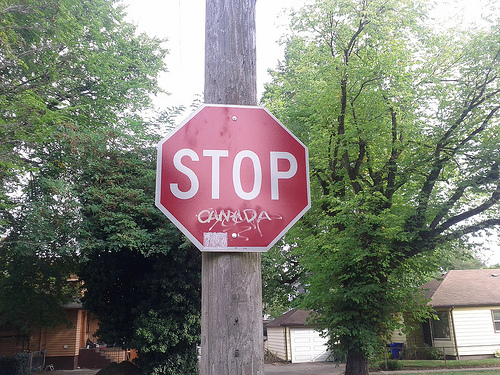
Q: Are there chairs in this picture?
A: No, there are no chairs.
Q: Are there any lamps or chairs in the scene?
A: No, there are no chairs or lamps.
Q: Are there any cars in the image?
A: No, there are no cars.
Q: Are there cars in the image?
A: No, there are no cars.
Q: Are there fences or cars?
A: No, there are no cars or fences.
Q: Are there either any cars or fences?
A: No, there are no cars or fences.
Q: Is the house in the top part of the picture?
A: No, the house is in the bottom of the image.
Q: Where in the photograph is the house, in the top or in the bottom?
A: The house is in the bottom of the image.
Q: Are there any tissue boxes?
A: No, there are no tissue boxes.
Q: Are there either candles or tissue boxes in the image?
A: No, there are no tissue boxes or candles.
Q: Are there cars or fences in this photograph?
A: No, there are no cars or fences.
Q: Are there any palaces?
A: No, there are no palaces.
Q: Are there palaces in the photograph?
A: No, there are no palaces.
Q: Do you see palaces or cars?
A: No, there are no palaces or cars.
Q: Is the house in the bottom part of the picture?
A: Yes, the house is in the bottom of the image.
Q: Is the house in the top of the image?
A: No, the house is in the bottom of the image.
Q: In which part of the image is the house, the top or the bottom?
A: The house is in the bottom of the image.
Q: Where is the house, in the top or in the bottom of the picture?
A: The house is in the bottom of the image.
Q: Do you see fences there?
A: No, there are no fences.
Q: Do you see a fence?
A: No, there are no fences.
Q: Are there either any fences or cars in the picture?
A: No, there are no fences or cars.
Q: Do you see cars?
A: No, there are no cars.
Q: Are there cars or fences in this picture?
A: No, there are no cars or fences.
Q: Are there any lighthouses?
A: No, there are no lighthouses.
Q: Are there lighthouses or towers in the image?
A: No, there are no lighthouses or towers.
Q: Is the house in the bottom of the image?
A: Yes, the house is in the bottom of the image.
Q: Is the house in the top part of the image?
A: No, the house is in the bottom of the image.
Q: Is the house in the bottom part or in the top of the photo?
A: The house is in the bottom of the image.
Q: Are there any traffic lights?
A: No, there are no traffic lights.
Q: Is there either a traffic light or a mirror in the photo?
A: No, there are no traffic lights or mirrors.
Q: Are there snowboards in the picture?
A: No, there are no snowboards.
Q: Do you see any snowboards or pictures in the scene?
A: No, there are no snowboards or pictures.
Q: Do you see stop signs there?
A: Yes, there is a stop sign.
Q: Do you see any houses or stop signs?
A: Yes, there is a stop sign.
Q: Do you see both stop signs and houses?
A: Yes, there are both a stop sign and a house.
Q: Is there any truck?
A: No, there are no trucks.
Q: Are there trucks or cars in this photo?
A: No, there are no trucks or cars.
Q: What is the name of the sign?
A: The sign is a stop sign.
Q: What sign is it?
A: The sign is a stop sign.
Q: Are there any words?
A: Yes, there are words.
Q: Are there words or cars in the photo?
A: Yes, there are words.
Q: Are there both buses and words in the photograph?
A: No, there are words but no buses.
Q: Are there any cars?
A: No, there are no cars.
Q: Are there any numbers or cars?
A: No, there are no cars or numbers.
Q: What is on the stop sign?
A: The words are on the stop sign.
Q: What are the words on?
A: The words are on the stop sign.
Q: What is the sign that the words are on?
A: The sign is a stop sign.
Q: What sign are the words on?
A: The words are on the stop sign.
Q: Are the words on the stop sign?
A: Yes, the words are on the stop sign.